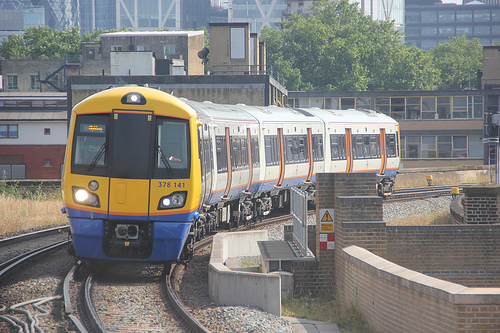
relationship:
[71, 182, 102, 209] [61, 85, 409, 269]
light on train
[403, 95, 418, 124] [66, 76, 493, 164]
window on building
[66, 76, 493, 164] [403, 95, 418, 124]
building with a window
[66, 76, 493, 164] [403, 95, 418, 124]
building with a glass window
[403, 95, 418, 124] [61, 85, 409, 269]
window on train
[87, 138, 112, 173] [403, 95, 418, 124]
wiper on window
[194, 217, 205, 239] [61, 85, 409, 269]
wheel on train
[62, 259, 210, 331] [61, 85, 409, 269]
tracks with a train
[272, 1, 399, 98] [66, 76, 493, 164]
tree behind building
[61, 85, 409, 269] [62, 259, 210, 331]
train on tracks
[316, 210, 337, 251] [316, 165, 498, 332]
sign on wall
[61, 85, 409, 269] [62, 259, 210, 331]
train on long tracks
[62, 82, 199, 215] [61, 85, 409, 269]
yellow front train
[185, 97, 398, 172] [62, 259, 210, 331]
gray train tracks